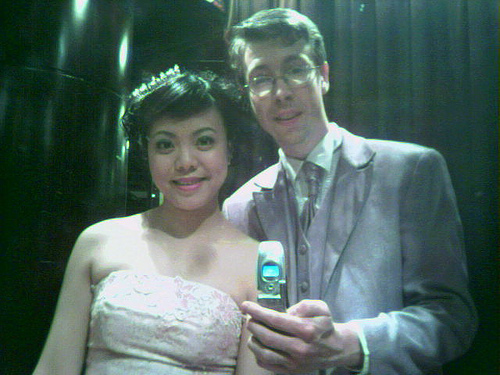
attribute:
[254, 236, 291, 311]
cell phone — active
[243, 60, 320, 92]
glasses — eye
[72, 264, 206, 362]
dress — white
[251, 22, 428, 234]
people — posing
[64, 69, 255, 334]
people — posing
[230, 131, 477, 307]
coat — purple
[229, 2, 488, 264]
curtain — maroon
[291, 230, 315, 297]
buttons — purple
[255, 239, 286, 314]
phone — held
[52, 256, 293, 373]
dress — pink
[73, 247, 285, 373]
dress — pink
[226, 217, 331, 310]
cell phone — silver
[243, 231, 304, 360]
cell phone — silver